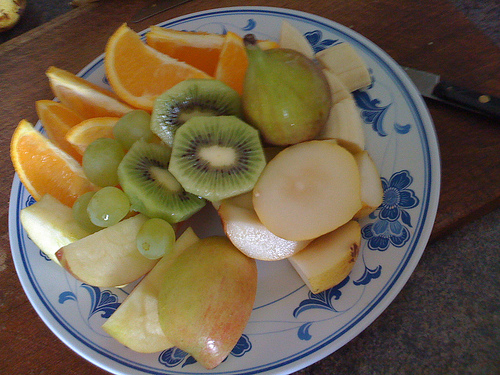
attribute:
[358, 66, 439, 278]
plate — blue, white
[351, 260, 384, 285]
plate — white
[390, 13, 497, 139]
board — wooden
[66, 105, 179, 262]
grapes — green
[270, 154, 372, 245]
slice — kiwi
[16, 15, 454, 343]
plate — white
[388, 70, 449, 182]
design — blue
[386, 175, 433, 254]
blue plate — white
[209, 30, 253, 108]
slice — orange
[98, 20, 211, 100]
orange — sliced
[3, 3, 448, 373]
plate — white, sliced, blue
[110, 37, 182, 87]
slice — orange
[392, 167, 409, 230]
design — blue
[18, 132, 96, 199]
fruit — sliced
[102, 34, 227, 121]
fruit — sliced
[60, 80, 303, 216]
fruit — sliced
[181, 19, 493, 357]
plate — white, blue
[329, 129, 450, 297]
design — blue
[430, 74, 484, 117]
handle — black